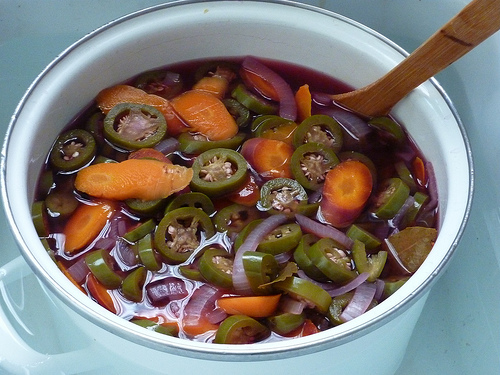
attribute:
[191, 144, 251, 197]
pepper — green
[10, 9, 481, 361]
pot — white, silver, large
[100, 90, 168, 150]
pepper — green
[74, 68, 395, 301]
soup — vegetable, mixture, liquid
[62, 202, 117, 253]
carrot — orange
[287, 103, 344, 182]
jalapeno — present, round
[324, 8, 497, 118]
spoon — wood, brown, wooden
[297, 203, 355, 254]
onions — red, purple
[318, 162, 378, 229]
carrot — chunky